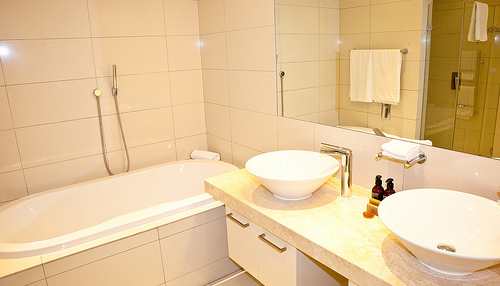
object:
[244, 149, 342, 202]
sink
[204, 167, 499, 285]
counter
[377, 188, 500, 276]
sink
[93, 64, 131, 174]
hose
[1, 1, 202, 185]
wall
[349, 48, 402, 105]
towel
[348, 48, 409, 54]
bar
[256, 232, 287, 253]
handles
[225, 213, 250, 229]
drawer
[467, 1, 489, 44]
towel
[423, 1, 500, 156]
door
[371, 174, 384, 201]
toiletries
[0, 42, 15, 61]
light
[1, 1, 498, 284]
room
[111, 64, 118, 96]
shower head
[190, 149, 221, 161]
towel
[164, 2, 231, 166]
corner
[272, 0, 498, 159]
mirror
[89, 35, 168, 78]
tile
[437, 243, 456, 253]
drain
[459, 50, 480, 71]
cloth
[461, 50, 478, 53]
holder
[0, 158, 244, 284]
tub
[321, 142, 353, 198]
faucet